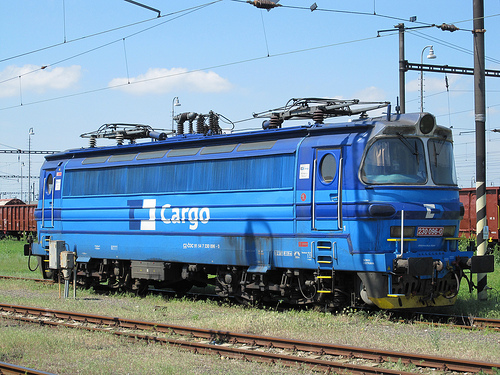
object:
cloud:
[105, 64, 235, 96]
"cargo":
[159, 200, 212, 232]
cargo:
[158, 197, 216, 233]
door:
[308, 145, 344, 232]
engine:
[128, 260, 167, 281]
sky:
[0, 0, 500, 188]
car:
[454, 182, 499, 244]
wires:
[95, 25, 151, 91]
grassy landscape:
[32, 335, 134, 369]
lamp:
[419, 46, 440, 62]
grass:
[2, 235, 497, 373]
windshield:
[348, 121, 459, 203]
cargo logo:
[124, 192, 213, 233]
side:
[21, 131, 431, 283]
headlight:
[416, 111, 437, 140]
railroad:
[0, 268, 497, 328]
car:
[0, 202, 38, 236]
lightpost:
[418, 44, 438, 114]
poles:
[474, 0, 488, 309]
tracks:
[4, 289, 498, 373]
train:
[29, 96, 474, 315]